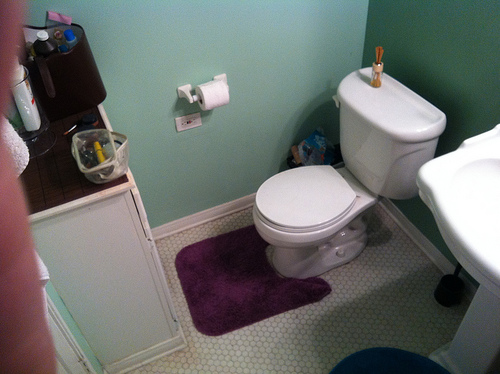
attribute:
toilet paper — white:
[191, 77, 232, 113]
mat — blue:
[325, 340, 453, 372]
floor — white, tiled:
[122, 174, 498, 371]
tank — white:
[331, 65, 447, 200]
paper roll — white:
[193, 79, 230, 110]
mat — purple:
[173, 219, 332, 337]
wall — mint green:
[118, 23, 312, 170]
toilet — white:
[230, 60, 452, 260]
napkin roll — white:
[194, 81, 232, 108]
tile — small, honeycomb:
[228, 331, 315, 371]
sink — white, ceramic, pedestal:
[403, 121, 492, 364]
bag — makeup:
[70, 127, 130, 184]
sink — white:
[408, 182, 499, 311]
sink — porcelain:
[412, 118, 497, 368]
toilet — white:
[241, 53, 458, 296]